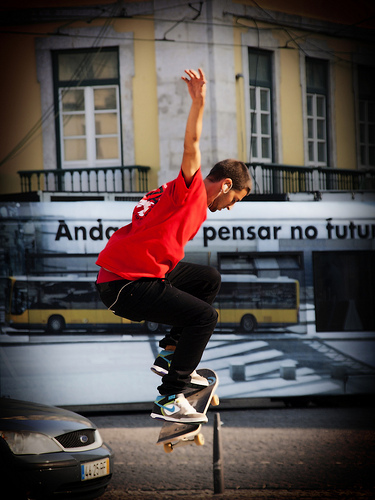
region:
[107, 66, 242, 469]
boy is doing skateboard trick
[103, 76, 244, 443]
boy is doing skateboard trick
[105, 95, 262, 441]
boy is doing skateboard trick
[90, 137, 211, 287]
the shirt is red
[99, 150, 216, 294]
the shirt is red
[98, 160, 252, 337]
the shirt is red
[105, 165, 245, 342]
the shirt is red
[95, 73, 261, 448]
a man skateboarding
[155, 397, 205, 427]
man is wearing shoes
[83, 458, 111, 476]
license plate on the car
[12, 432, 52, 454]
headlight on the car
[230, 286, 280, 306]
windows on the bus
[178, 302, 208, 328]
the pants are black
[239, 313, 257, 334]
back tire on the bus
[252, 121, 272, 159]
a window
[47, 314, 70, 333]
front tire of the bus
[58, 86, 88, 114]
Small pane of glass in the window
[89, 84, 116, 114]
Small pane of glass in the window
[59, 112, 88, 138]
Small pane of glass in the window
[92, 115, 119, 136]
Small pane of glass in the window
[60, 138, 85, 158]
Small pane of glass in the window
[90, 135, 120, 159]
Small pane of glass in the window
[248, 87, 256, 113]
Small pane of glass in the window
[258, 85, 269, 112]
Small pane of glass in the window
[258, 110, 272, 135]
Small pane of glass in the window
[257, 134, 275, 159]
Small pane of glass in the window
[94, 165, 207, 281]
the shirt is red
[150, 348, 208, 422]
the shoes on the skateboard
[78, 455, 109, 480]
the license plate on the car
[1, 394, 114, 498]
the car with the license plate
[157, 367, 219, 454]
the skateboard under the shoes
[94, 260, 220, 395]
the pants are black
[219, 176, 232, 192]
the ear on the man's head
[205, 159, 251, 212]
the head on the man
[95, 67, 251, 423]
the man on the skateboard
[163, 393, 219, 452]
the wheels under the skateboard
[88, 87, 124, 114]
Small pane of glass in the window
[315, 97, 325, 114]
Small pane of glass in the window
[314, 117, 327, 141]
Small pane of glass in the window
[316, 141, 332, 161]
Small pane of glass in the window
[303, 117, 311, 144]
Small pane of glass in the window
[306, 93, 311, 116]
Small pane of glass in the window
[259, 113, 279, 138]
Small pane of glass in the window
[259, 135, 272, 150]
Small pane of glass in the window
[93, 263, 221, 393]
a black pair of jeans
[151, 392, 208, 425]
a grey white and blue athletic shoe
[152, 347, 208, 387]
a grey white and blue athletic shoe